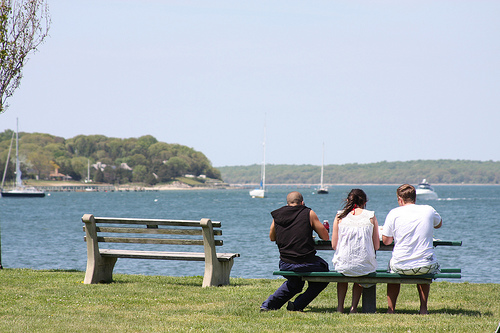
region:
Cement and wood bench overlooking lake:
[78, 211, 238, 286]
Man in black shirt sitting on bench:
[257, 191, 327, 312]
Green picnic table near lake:
[273, 235, 463, 307]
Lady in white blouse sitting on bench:
[330, 185, 381, 310]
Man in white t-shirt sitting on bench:
[380, 180, 443, 314]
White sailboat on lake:
[246, 146, 267, 198]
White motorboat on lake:
[405, 176, 443, 196]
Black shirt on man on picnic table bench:
[270, 203, 315, 263]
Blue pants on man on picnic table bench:
[261, 280, 328, 306]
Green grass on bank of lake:
[1, 269, 497, 331]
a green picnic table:
[272, 235, 462, 290]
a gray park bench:
[70, 200, 240, 285]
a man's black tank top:
[270, 200, 315, 255]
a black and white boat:
[0, 115, 45, 195]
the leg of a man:
[382, 270, 402, 302]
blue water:
[0, 180, 496, 280]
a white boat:
[405, 175, 445, 197]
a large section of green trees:
[0, 125, 225, 180]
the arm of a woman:
[330, 207, 341, 256]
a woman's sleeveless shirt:
[331, 209, 381, 274]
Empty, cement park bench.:
[73, 198, 240, 302]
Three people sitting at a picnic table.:
[253, 175, 468, 331]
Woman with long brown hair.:
[332, 181, 374, 221]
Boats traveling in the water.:
[239, 154, 335, 202]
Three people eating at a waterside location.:
[251, 172, 479, 319]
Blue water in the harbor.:
[50, 190, 228, 215]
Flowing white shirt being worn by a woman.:
[331, 207, 381, 279]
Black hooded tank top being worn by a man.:
[265, 200, 327, 267]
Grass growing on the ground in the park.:
[17, 290, 233, 324]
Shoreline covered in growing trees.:
[9, 118, 229, 193]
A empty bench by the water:
[67, 200, 262, 278]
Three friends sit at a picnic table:
[256, 177, 498, 322]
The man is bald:
[251, 179, 326, 330]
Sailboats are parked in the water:
[232, 122, 342, 200]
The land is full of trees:
[62, 100, 224, 192]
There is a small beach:
[66, 152, 226, 209]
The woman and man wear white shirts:
[335, 186, 471, 278]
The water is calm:
[148, 185, 243, 233]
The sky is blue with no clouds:
[207, 69, 243, 107]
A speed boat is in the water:
[409, 176, 442, 211]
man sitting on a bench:
[265, 190, 330, 314]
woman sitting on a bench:
[330, 188, 382, 310]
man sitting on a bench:
[383, 185, 443, 310]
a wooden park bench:
[77, 210, 238, 287]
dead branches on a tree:
[0, 0, 52, 110]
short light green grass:
[0, 286, 257, 331]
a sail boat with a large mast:
[0, 112, 47, 196]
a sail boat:
[315, 132, 333, 196]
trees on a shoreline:
[59, 134, 235, 193]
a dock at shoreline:
[42, 182, 169, 192]